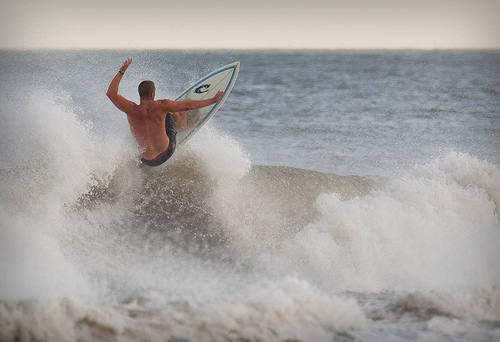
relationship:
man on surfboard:
[108, 56, 218, 160] [110, 45, 244, 181]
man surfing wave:
[108, 56, 228, 170] [294, 181, 463, 311]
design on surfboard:
[187, 80, 216, 98] [148, 62, 238, 150]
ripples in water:
[297, 59, 428, 141] [9, 177, 467, 330]